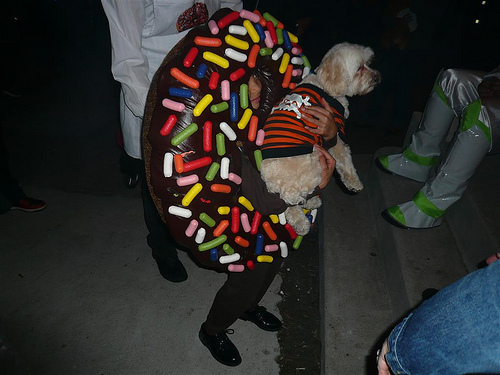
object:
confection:
[183, 47, 199, 68]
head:
[315, 41, 382, 97]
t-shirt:
[261, 83, 349, 159]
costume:
[139, 7, 318, 273]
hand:
[302, 98, 337, 141]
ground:
[368, 178, 386, 191]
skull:
[271, 93, 312, 119]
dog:
[260, 42, 381, 237]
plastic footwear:
[378, 67, 500, 230]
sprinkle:
[171, 122, 198, 146]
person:
[97, 0, 264, 281]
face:
[248, 73, 263, 110]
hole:
[247, 68, 269, 113]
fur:
[261, 43, 382, 236]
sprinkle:
[163, 152, 173, 178]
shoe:
[240, 304, 284, 331]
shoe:
[382, 102, 500, 231]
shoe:
[376, 64, 479, 183]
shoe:
[148, 243, 189, 283]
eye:
[356, 65, 365, 71]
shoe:
[198, 325, 242, 366]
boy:
[199, 73, 338, 367]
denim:
[384, 259, 500, 374]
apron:
[101, 0, 243, 160]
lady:
[198, 66, 338, 367]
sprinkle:
[221, 80, 231, 101]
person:
[377, 57, 499, 230]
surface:
[374, 265, 499, 375]